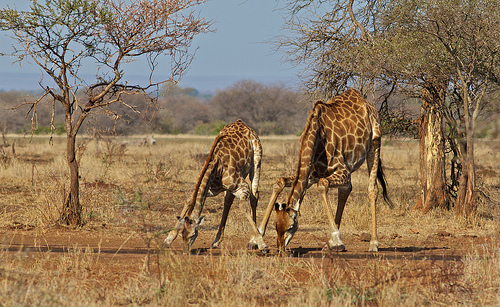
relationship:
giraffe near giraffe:
[249, 87, 395, 252] [161, 117, 271, 253]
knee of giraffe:
[272, 176, 285, 193] [249, 87, 395, 252]